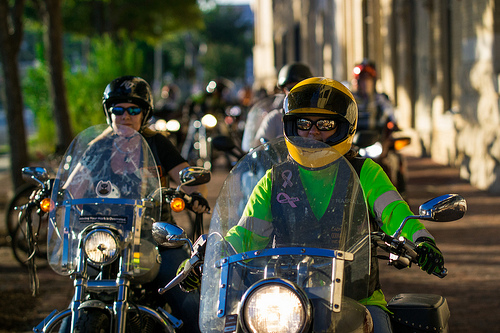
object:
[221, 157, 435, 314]
shirt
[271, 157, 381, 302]
vest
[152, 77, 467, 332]
man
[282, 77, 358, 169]
helmet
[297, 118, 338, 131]
sunglasses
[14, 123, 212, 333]
motorcycle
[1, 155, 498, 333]
road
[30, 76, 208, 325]
woman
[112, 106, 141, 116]
sunglasses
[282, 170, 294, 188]
ribbon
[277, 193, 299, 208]
ribbon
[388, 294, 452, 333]
saddlebag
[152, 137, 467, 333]
motorcycle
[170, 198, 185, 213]
light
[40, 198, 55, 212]
light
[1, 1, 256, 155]
trees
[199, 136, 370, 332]
windshield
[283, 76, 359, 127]
visor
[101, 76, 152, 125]
helmet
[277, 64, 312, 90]
helmet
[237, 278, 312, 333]
headlight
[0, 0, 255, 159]
tree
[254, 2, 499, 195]
building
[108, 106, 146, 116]
lenses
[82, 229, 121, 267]
light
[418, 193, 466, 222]
mirror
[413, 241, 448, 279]
glove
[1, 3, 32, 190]
trunk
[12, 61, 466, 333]
rally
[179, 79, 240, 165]
person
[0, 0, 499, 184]
background